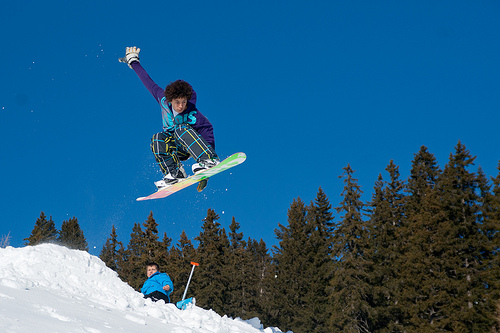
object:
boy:
[118, 46, 220, 192]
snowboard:
[136, 152, 247, 201]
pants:
[150, 124, 218, 177]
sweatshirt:
[130, 61, 215, 151]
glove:
[118, 46, 140, 69]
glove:
[197, 178, 210, 193]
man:
[141, 263, 175, 304]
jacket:
[140, 272, 174, 303]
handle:
[177, 261, 200, 310]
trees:
[403, 141, 500, 332]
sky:
[1, 0, 500, 259]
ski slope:
[0, 242, 281, 333]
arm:
[131, 62, 166, 102]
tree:
[326, 162, 385, 332]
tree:
[260, 186, 328, 333]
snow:
[222, 172, 234, 214]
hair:
[165, 79, 193, 102]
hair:
[146, 262, 159, 271]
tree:
[198, 208, 227, 318]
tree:
[27, 211, 58, 246]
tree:
[57, 217, 89, 252]